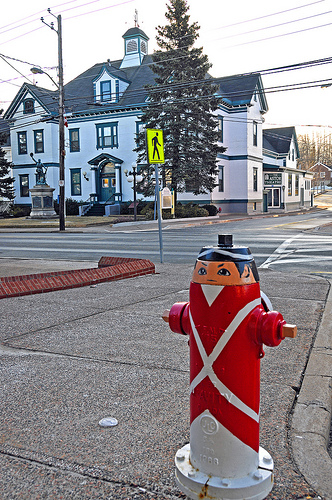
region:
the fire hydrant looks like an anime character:
[165, 233, 288, 499]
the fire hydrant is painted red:
[162, 232, 293, 497]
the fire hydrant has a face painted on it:
[189, 246, 258, 283]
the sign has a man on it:
[146, 127, 166, 265]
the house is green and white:
[5, 26, 317, 214]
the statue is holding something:
[28, 151, 56, 216]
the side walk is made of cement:
[1, 257, 330, 498]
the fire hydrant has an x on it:
[187, 282, 264, 451]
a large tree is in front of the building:
[140, 0, 216, 216]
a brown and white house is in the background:
[308, 166, 330, 185]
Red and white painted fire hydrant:
[149, 221, 304, 498]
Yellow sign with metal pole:
[134, 118, 177, 278]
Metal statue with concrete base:
[21, 142, 59, 230]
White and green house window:
[87, 57, 131, 112]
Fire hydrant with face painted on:
[134, 214, 309, 499]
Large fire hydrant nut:
[272, 310, 309, 347]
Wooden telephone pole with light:
[26, 10, 76, 242]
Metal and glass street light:
[21, 61, 59, 93]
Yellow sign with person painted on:
[143, 121, 172, 174]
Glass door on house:
[257, 182, 289, 213]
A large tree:
[138, 0, 208, 209]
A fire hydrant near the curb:
[159, 243, 330, 499]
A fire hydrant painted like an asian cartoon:
[161, 232, 275, 499]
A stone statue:
[25, 148, 57, 219]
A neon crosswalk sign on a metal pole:
[146, 128, 167, 262]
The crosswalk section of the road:
[257, 223, 330, 277]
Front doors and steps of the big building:
[80, 161, 118, 213]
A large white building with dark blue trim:
[0, 0, 262, 206]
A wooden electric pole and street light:
[27, 57, 76, 234]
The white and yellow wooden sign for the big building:
[149, 183, 180, 220]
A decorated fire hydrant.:
[141, 218, 297, 482]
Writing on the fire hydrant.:
[177, 308, 237, 484]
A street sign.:
[135, 127, 177, 259]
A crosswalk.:
[255, 190, 326, 277]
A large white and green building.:
[6, 16, 306, 216]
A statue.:
[21, 147, 54, 213]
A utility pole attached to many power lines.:
[30, 2, 92, 231]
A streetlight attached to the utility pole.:
[25, 63, 74, 109]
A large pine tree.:
[140, 0, 225, 211]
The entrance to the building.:
[84, 151, 120, 208]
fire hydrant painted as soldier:
[169, 228, 292, 482]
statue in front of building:
[19, 146, 59, 228]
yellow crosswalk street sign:
[130, 117, 174, 175]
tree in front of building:
[130, 3, 223, 205]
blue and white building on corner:
[17, 78, 323, 229]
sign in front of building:
[152, 184, 185, 232]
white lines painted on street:
[268, 227, 331, 288]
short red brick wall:
[2, 247, 168, 300]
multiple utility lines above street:
[9, 17, 327, 98]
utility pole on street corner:
[37, 1, 81, 238]